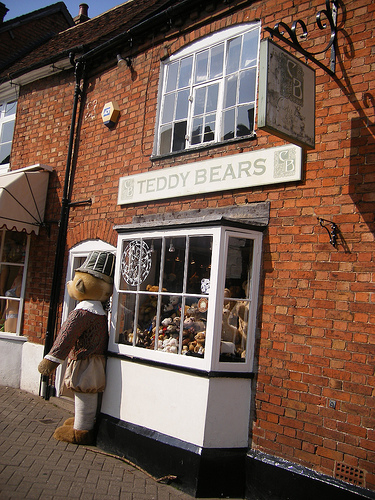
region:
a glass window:
[147, 41, 254, 156]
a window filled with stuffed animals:
[121, 240, 246, 360]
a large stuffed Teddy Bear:
[38, 253, 118, 447]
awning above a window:
[0, 166, 58, 229]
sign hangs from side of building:
[260, 40, 323, 148]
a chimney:
[71, 0, 92, 21]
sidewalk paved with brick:
[1, 383, 54, 488]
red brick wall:
[266, 250, 359, 453]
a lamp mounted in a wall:
[112, 50, 137, 81]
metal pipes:
[50, 91, 84, 337]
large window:
[154, 15, 271, 160]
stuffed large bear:
[39, 245, 122, 451]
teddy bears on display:
[105, 226, 264, 363]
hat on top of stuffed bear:
[71, 245, 117, 301]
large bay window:
[100, 208, 269, 453]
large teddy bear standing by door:
[38, 248, 125, 450]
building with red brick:
[9, 15, 373, 465]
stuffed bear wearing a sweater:
[37, 298, 119, 368]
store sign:
[246, 24, 337, 149]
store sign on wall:
[101, 143, 321, 211]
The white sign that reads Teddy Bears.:
[115, 147, 300, 207]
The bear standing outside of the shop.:
[35, 250, 114, 446]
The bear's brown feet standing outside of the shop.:
[50, 413, 89, 450]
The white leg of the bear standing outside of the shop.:
[72, 390, 93, 431]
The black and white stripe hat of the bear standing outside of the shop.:
[76, 245, 115, 280]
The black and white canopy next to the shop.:
[2, 174, 45, 236]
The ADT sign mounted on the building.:
[95, 101, 121, 127]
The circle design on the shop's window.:
[120, 236, 155, 288]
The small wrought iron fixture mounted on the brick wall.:
[312, 212, 344, 251]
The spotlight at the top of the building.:
[109, 48, 135, 75]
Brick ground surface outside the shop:
[8, 443, 80, 487]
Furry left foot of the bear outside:
[53, 424, 94, 445]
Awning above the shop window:
[2, 175, 44, 236]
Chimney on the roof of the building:
[72, 3, 93, 21]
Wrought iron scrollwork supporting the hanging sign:
[267, 11, 339, 57]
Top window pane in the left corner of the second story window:
[156, 50, 183, 99]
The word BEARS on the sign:
[191, 165, 275, 183]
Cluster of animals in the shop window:
[151, 289, 201, 348]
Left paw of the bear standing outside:
[35, 358, 61, 376]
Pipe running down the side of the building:
[62, 79, 82, 200]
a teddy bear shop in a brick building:
[30, 54, 340, 468]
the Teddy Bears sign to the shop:
[117, 140, 302, 212]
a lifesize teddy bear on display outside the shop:
[39, 249, 115, 446]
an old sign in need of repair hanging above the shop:
[253, 74, 322, 145]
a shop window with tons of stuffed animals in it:
[119, 236, 250, 364]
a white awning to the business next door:
[2, 169, 58, 238]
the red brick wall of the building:
[268, 242, 373, 433]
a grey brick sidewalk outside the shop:
[4, 405, 61, 493]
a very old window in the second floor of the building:
[159, 77, 262, 150]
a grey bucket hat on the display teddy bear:
[72, 246, 120, 284]